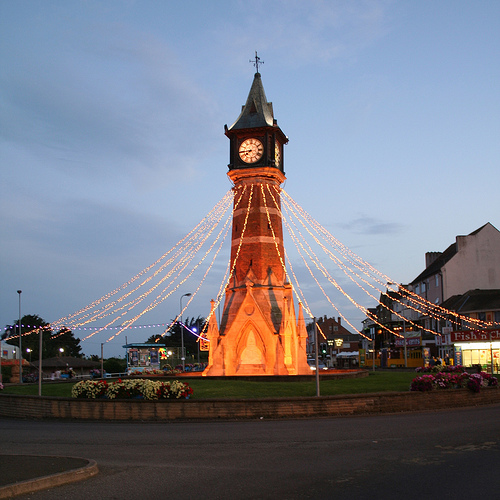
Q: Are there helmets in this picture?
A: No, there are no helmets.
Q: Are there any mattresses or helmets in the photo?
A: No, there are no helmets or mattresses.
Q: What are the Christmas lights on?
A: The Christmas lights are on the pole.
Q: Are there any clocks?
A: Yes, there is a clock.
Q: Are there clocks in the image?
A: Yes, there is a clock.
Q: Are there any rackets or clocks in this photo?
A: Yes, there is a clock.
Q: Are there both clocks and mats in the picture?
A: No, there is a clock but no mats.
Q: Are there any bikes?
A: No, there are no bikes.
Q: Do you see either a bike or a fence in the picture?
A: No, there are no bikes or fences.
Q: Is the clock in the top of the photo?
A: Yes, the clock is in the top of the image.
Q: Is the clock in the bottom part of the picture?
A: No, the clock is in the top of the image.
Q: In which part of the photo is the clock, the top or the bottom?
A: The clock is in the top of the image.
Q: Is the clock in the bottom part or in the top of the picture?
A: The clock is in the top of the image.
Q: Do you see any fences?
A: No, there are no fences.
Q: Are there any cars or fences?
A: No, there are no fences or cars.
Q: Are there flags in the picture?
A: No, there are no flags.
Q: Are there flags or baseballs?
A: No, there are no flags or baseballs.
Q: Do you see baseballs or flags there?
A: No, there are no flags or baseballs.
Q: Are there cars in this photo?
A: No, there are no cars.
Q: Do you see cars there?
A: No, there are no cars.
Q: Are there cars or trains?
A: No, there are no cars or trains.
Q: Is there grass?
A: Yes, there is grass.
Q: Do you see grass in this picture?
A: Yes, there is grass.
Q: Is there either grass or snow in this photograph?
A: Yes, there is grass.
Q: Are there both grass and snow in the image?
A: No, there is grass but no snow.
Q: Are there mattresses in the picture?
A: No, there are no mattresses.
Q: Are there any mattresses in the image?
A: No, there are no mattresses.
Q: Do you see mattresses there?
A: No, there are no mattresses.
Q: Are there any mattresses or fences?
A: No, there are no mattresses or fences.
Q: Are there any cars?
A: No, there are no cars.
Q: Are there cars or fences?
A: No, there are no cars or fences.